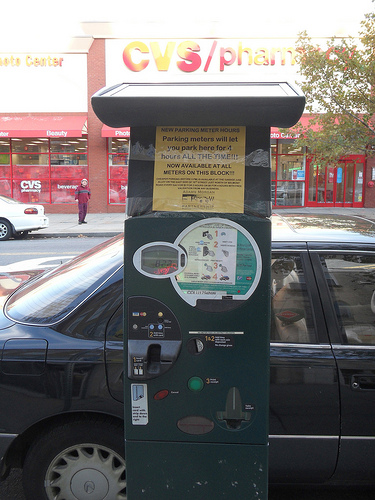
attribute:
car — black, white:
[1, 214, 373, 499]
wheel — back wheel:
[24, 415, 124, 499]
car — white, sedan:
[0, 193, 47, 244]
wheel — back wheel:
[0, 218, 13, 241]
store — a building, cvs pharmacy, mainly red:
[1, 0, 373, 216]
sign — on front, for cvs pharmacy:
[121, 39, 353, 83]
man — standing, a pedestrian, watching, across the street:
[74, 179, 93, 224]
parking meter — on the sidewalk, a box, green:
[92, 79, 308, 499]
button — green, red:
[188, 378, 204, 394]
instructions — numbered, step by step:
[172, 216, 263, 305]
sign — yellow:
[152, 123, 249, 220]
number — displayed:
[153, 259, 178, 273]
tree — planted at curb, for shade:
[282, 11, 373, 169]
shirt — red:
[76, 187, 92, 206]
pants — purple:
[77, 202, 90, 222]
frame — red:
[305, 151, 365, 164]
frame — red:
[306, 200, 364, 210]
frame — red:
[362, 155, 367, 202]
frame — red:
[305, 154, 313, 205]